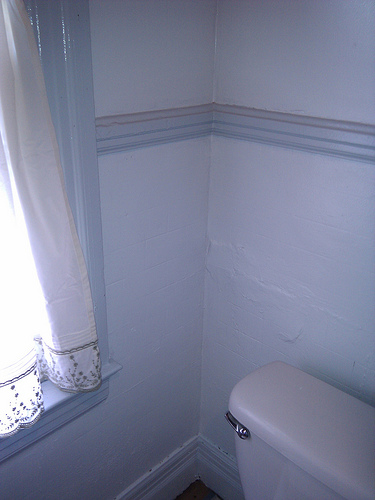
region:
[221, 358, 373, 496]
the tank is by the wall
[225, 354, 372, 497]
the tank is white in color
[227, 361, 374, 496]
the tank is made of ceramic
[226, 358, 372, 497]
the tank has a separate top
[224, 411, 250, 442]
the handle is made of metal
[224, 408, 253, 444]
the handle is made of steel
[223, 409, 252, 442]
the handle is on the tank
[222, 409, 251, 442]
the handle is chrome plated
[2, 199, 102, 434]
the window is on the left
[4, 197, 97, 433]
the window has a curtain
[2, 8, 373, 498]
a toilet tank in a bathroom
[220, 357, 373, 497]
toilet tank is white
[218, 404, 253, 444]
a silver handle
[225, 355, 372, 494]
a lid of a tank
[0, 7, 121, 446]
a window in a bathroom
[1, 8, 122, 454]
window has a white frame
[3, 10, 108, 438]
a white curtain on a window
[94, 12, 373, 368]
wall is color white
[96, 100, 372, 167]
decorations on the wall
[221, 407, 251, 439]
a toilet flush handle.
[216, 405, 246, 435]
a toilet flush handle.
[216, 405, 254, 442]
a toilet flush handle.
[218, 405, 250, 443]
a toilet flush handle.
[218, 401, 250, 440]
a toilet flush handle.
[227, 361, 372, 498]
the tank is against the wall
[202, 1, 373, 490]
the wall is white in color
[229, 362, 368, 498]
the tank has a cover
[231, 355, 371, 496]
the cover is white in color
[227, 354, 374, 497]
the cover is ceramic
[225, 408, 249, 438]
the handle is made of steel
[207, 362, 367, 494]
tank to a toilet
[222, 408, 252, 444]
handle for a toilet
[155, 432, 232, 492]
base board in a bathroom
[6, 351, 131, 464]
sill of a window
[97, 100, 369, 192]
molding on a wall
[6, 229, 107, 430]
curtain on a window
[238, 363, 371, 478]
lid on a toilet tank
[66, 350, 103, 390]
embroidery on a curtain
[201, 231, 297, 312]
patch on a wall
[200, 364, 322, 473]
A white commode tank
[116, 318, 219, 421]
A white cinderblock wall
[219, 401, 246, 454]
A silver handle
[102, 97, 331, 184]
Red and blue trim around the wall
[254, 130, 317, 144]
A blue line on the wall